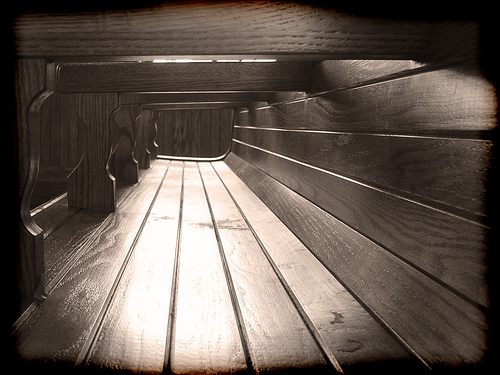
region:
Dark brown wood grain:
[199, 162, 228, 199]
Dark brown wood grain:
[255, 327, 312, 368]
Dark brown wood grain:
[192, 324, 239, 358]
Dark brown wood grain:
[138, 297, 177, 337]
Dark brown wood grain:
[47, 284, 103, 321]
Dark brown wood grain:
[98, 233, 155, 261]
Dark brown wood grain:
[153, 193, 210, 238]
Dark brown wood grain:
[199, 171, 246, 221]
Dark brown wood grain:
[207, 157, 282, 212]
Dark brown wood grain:
[245, 121, 300, 156]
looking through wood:
[159, 114, 228, 155]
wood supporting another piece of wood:
[67, 95, 115, 208]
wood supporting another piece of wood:
[0, 62, 46, 299]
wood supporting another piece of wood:
[119, 107, 138, 184]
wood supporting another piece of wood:
[135, 110, 152, 170]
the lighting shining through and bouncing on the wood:
[141, 204, 201, 341]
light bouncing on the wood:
[150, 175, 205, 325]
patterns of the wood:
[350, 196, 470, 277]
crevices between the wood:
[325, 63, 440, 97]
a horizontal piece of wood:
[58, 66, 312, 87]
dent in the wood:
[320, 297, 370, 372]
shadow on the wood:
[134, 139, 300, 369]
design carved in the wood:
[53, 92, 148, 232]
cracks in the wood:
[116, 206, 141, 326]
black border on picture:
[1, 1, 84, 21]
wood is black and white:
[19, 33, 483, 372]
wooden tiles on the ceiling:
[61, 35, 314, 121]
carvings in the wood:
[132, 192, 289, 240]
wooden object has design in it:
[3, 40, 213, 297]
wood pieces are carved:
[58, 75, 148, 240]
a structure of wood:
[8, 8, 487, 359]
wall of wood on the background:
[3, 8, 241, 180]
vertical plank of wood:
[5, 8, 64, 310]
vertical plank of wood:
[60, 88, 128, 221]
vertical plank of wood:
[110, 98, 147, 188]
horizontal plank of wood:
[44, 56, 313, 99]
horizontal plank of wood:
[6, 5, 460, 68]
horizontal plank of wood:
[151, 96, 235, 116]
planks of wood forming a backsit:
[234, 92, 499, 297]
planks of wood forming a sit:
[65, 146, 342, 357]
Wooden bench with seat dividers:
[4, 5, 499, 374]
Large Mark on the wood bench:
[123, 201, 264, 236]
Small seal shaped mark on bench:
[316, 307, 351, 327]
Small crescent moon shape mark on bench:
[334, 333, 366, 359]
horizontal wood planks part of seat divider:
[1, 2, 493, 92]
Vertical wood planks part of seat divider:
[11, 56, 159, 298]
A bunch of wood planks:
[3, 14, 490, 374]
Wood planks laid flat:
[6, 137, 390, 374]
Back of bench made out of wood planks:
[223, 18, 499, 373]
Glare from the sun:
[128, 145, 367, 362]